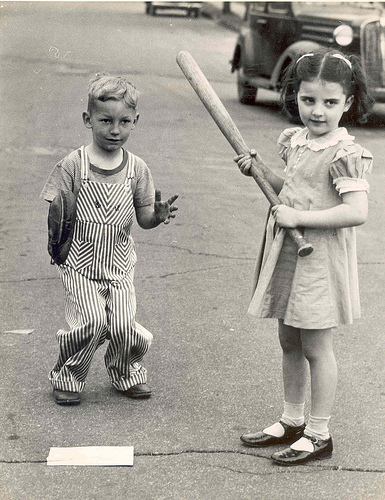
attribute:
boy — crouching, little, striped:
[39, 69, 184, 407]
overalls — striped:
[43, 148, 170, 399]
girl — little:
[237, 47, 371, 476]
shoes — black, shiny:
[235, 412, 349, 466]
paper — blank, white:
[41, 434, 145, 476]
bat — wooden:
[170, 45, 317, 260]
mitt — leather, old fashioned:
[37, 188, 90, 272]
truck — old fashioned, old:
[227, 3, 384, 130]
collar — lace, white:
[285, 121, 360, 159]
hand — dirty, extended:
[142, 184, 183, 231]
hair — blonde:
[78, 69, 144, 120]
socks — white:
[252, 398, 341, 456]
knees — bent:
[63, 303, 158, 348]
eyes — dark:
[299, 90, 346, 111]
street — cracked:
[2, 3, 385, 496]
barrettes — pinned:
[292, 48, 357, 73]